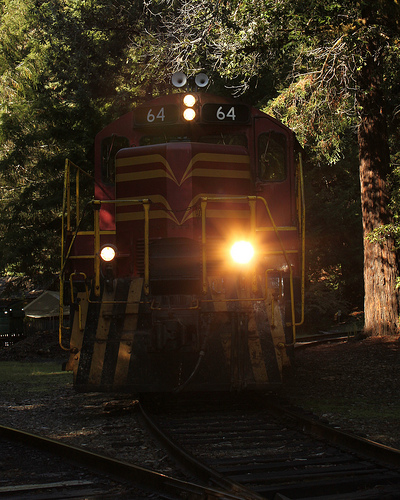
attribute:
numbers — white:
[141, 101, 243, 125]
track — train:
[127, 392, 399, 496]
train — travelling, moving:
[56, 68, 367, 399]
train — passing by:
[47, 61, 324, 457]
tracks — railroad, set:
[141, 397, 395, 497]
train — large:
[40, 46, 340, 451]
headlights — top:
[181, 93, 201, 122]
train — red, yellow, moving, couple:
[48, 64, 309, 402]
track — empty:
[4, 383, 398, 497]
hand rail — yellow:
[56, 155, 309, 353]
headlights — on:
[86, 88, 312, 304]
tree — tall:
[3, 33, 380, 120]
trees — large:
[269, 22, 388, 144]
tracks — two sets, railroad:
[136, 400, 356, 462]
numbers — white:
[214, 105, 243, 126]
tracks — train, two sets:
[6, 400, 398, 496]